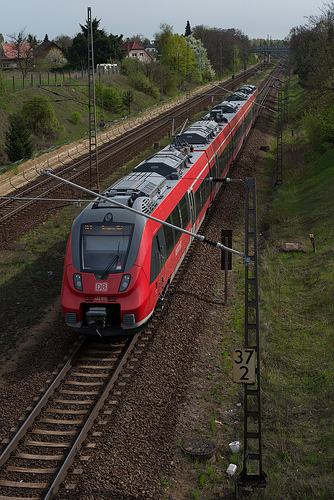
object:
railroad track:
[1, 335, 147, 499]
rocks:
[5, 101, 267, 494]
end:
[60, 208, 158, 338]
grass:
[194, 305, 238, 492]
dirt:
[160, 291, 246, 493]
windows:
[162, 104, 256, 260]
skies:
[2, 3, 326, 38]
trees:
[285, 0, 333, 95]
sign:
[221, 229, 233, 271]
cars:
[60, 83, 261, 342]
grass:
[258, 79, 334, 499]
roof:
[1, 42, 34, 60]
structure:
[87, 7, 99, 194]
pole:
[224, 237, 228, 305]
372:
[234, 349, 255, 380]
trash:
[226, 440, 240, 477]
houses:
[2, 39, 71, 75]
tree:
[3, 26, 44, 89]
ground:
[176, 301, 220, 497]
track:
[0, 331, 143, 499]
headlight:
[118, 273, 131, 292]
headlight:
[73, 272, 83, 291]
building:
[0, 33, 69, 71]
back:
[221, 229, 233, 271]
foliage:
[3, 109, 35, 162]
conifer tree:
[0, 111, 38, 164]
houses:
[96, 37, 159, 75]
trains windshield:
[78, 220, 135, 274]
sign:
[232, 347, 255, 385]